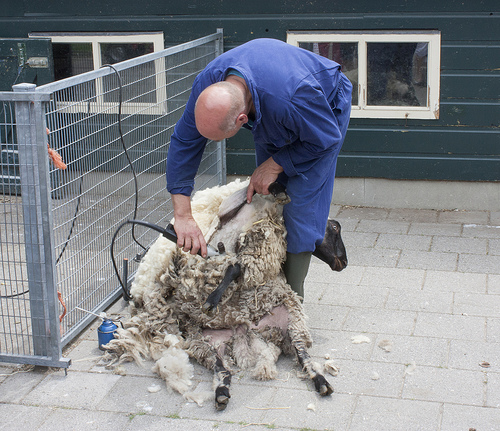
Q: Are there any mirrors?
A: No, there are no mirrors.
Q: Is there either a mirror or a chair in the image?
A: No, there are no mirrors or chairs.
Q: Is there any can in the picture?
A: Yes, there is a can.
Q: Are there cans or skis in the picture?
A: Yes, there is a can.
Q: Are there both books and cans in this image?
A: No, there is a can but no books.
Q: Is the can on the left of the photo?
A: Yes, the can is on the left of the image.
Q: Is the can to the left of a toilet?
A: No, the can is to the left of a man.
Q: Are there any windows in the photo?
A: Yes, there is a window.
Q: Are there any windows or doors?
A: Yes, there is a window.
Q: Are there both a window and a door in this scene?
A: No, there is a window but no doors.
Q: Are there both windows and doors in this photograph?
A: No, there is a window but no doors.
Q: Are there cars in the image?
A: No, there are no cars.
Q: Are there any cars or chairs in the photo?
A: No, there are no cars or chairs.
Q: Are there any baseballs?
A: No, there are no baseballs.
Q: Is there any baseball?
A: No, there are no baseballs.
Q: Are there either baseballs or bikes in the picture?
A: No, there are no baseballs or bikes.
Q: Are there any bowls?
A: No, there are no bowls.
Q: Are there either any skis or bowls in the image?
A: No, there are no bowls or skis.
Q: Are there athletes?
A: No, there are no athletes.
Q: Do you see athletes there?
A: No, there are no athletes.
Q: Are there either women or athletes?
A: No, there are no athletes or women.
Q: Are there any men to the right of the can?
A: Yes, there is a man to the right of the can.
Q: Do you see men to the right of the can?
A: Yes, there is a man to the right of the can.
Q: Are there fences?
A: Yes, there is a fence.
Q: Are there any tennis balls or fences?
A: Yes, there is a fence.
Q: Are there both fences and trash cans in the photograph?
A: No, there is a fence but no trash cans.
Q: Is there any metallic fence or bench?
A: Yes, there is a metal fence.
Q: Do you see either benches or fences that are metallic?
A: Yes, the fence is metallic.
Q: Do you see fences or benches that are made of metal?
A: Yes, the fence is made of metal.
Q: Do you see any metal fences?
A: Yes, there is a fence that is made of metal.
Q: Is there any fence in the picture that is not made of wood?
A: Yes, there is a fence that is made of metal.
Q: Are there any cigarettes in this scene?
A: No, there are no cigarettes.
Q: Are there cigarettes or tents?
A: No, there are no cigarettes or tents.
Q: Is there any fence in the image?
A: Yes, there is a fence.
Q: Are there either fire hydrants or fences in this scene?
A: Yes, there is a fence.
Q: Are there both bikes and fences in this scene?
A: No, there is a fence but no bikes.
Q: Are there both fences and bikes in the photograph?
A: No, there is a fence but no bikes.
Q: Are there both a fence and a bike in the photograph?
A: No, there is a fence but no bikes.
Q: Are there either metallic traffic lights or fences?
A: Yes, there is a metal fence.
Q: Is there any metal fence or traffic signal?
A: Yes, there is a metal fence.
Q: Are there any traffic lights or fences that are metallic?
A: Yes, the fence is metallic.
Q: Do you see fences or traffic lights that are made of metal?
A: Yes, the fence is made of metal.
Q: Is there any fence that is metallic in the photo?
A: Yes, there is a metal fence.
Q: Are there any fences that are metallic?
A: Yes, there is a fence that is metallic.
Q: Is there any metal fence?
A: Yes, there is a fence that is made of metal.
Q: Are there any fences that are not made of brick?
A: Yes, there is a fence that is made of metal.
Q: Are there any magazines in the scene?
A: No, there are no magazines.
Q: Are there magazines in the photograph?
A: No, there are no magazines.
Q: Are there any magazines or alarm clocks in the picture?
A: No, there are no magazines or alarm clocks.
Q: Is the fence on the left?
A: Yes, the fence is on the left of the image.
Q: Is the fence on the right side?
A: No, the fence is on the left of the image.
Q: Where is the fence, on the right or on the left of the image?
A: The fence is on the left of the image.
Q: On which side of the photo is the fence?
A: The fence is on the left of the image.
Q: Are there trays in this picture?
A: No, there are no trays.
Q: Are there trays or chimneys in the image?
A: No, there are no trays or chimneys.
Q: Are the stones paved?
A: Yes, the stones are paved.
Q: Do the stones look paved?
A: Yes, the stones are paved.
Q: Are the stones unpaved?
A: No, the stones are paved.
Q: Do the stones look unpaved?
A: No, the stones are paved.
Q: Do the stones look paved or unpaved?
A: The stones are paved.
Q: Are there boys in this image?
A: No, there are no boys.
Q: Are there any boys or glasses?
A: No, there are no boys or glasses.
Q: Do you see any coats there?
A: Yes, there is a coat.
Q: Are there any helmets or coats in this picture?
A: Yes, there is a coat.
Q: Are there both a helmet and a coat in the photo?
A: No, there is a coat but no helmets.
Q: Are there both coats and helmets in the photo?
A: No, there is a coat but no helmets.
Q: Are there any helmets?
A: No, there are no helmets.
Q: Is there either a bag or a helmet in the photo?
A: No, there are no helmets or bags.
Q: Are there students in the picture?
A: No, there are no students.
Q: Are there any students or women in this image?
A: No, there are no students or women.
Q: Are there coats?
A: Yes, there is a coat.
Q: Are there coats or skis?
A: Yes, there is a coat.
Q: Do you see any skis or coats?
A: Yes, there is a coat.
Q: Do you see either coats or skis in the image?
A: Yes, there is a coat.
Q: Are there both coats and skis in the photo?
A: No, there is a coat but no skis.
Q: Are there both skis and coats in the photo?
A: No, there is a coat but no skis.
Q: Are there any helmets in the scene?
A: No, there are no helmets.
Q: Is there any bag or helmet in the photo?
A: No, there are no helmets or bags.